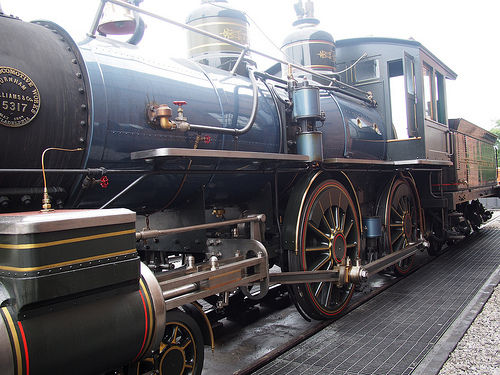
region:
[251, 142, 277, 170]
part of a train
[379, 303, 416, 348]
part of a floor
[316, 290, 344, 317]
part of a wheel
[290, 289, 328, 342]
edge of a wheel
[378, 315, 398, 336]
part of a floor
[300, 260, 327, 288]
part of a metal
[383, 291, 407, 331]
part of a floor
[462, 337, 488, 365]
part of a ground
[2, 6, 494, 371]
Restored steam engine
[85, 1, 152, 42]
train bell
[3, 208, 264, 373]
steam piston that drives the train engine wheels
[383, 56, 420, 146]
train engine cabin door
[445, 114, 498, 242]
Coal care behind the train engine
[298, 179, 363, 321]
Driven wheel on steam engine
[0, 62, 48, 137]
Manufacturers's nameplate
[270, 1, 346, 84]
engine smoke stack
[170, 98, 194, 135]
valve with red handle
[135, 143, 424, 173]
engine running board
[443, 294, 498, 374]
The gravel on the ground is gray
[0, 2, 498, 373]
The train sitting on the track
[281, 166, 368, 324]
The wheel of the train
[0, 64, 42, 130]
The name brand on the train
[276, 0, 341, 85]
The tank on the train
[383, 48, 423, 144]
The door to the train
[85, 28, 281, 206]
The fuel area of the train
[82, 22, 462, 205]
The train is blue and glossy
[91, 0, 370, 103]
A steel pipe on the train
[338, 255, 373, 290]
The bolt on the wheel holding it together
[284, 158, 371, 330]
Wheel of a train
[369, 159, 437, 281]
Wheel of a train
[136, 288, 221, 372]
Wheel of a train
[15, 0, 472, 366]
This is a train engine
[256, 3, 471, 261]
This is a train engine head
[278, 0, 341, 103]
This is a train engine tank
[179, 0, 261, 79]
This is a train engine tank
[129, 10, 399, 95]
This is a train engine pipe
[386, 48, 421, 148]
This is a train engine door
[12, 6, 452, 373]
a vintage train engine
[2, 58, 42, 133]
A plaque on a train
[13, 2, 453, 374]
A vintage steam engine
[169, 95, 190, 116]
a red knob on a train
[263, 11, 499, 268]
A train pulling a coal car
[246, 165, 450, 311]
Wheels on a train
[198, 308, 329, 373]
A track for a train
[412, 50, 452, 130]
Windows on a train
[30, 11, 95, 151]
Rivets on a train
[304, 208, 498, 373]
A walkway near a train